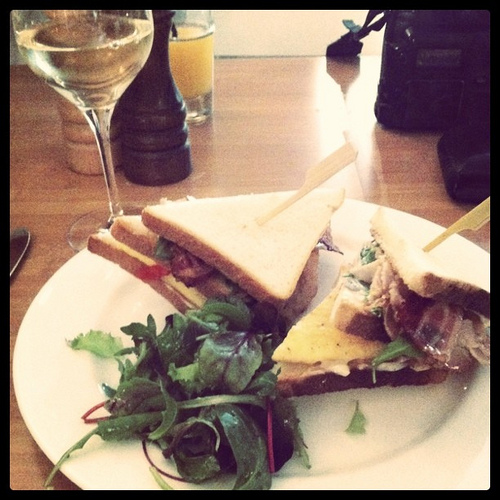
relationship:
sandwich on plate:
[139, 226, 423, 407] [66, 160, 490, 450]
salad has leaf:
[43, 297, 313, 490] [367, 336, 424, 387]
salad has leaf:
[43, 297, 313, 490] [341, 394, 371, 438]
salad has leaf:
[43, 297, 313, 490] [67, 327, 124, 362]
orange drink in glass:
[164, 26, 213, 91] [168, 19, 215, 128]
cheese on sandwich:
[269, 272, 398, 367] [83, 183, 490, 397]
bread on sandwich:
[371, 206, 488, 317] [86, 189, 345, 336]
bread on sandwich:
[145, 186, 345, 295] [264, 210, 495, 397]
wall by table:
[211, 14, 378, 58] [31, 25, 498, 393]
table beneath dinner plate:
[10, 57, 490, 490] [9, 196, 492, 490]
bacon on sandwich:
[405, 293, 462, 362] [277, 201, 483, 405]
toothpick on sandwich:
[421, 179, 476, 264] [244, 221, 469, 389]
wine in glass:
[14, 15, 153, 110] [10, 8, 155, 253]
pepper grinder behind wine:
[107, 43, 232, 198] [39, 31, 148, 94]